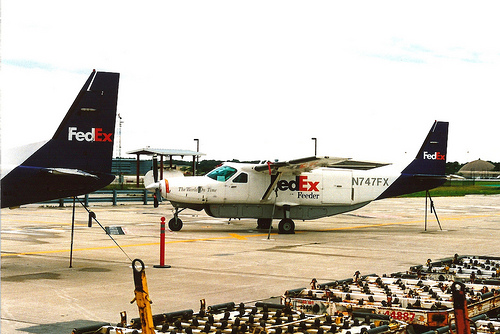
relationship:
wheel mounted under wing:
[277, 217, 296, 234] [253, 153, 352, 203]